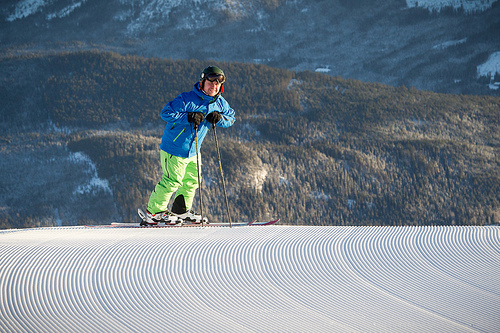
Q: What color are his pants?
A: Green.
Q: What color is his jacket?
A: Blue.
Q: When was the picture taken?
A: In the daytime.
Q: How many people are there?
A: 1.